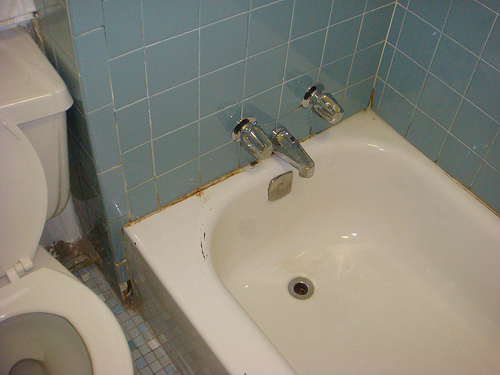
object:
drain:
[287, 276, 314, 300]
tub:
[121, 109, 500, 375]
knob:
[231, 116, 273, 160]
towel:
[0, 0, 36, 31]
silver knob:
[299, 83, 345, 125]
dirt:
[48, 240, 97, 273]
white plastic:
[0, 31, 74, 221]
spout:
[267, 126, 315, 178]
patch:
[268, 171, 294, 202]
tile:
[355, 2, 397, 52]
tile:
[282, 27, 328, 81]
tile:
[429, 33, 481, 97]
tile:
[449, 97, 499, 159]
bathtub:
[121, 108, 499, 375]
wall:
[29, 0, 137, 305]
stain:
[123, 159, 259, 228]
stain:
[296, 126, 331, 143]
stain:
[364, 108, 368, 112]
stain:
[432, 160, 500, 217]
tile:
[120, 140, 155, 190]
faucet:
[267, 126, 315, 178]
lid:
[0, 113, 48, 278]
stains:
[95, 228, 146, 322]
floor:
[69, 263, 181, 374]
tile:
[144, 29, 200, 97]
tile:
[198, 59, 246, 119]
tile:
[132, 335, 146, 348]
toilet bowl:
[0, 266, 135, 375]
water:
[9, 332, 74, 371]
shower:
[268, 126, 316, 178]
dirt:
[200, 223, 208, 260]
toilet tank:
[0, 26, 74, 221]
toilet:
[0, 26, 135, 375]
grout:
[122, 169, 242, 229]